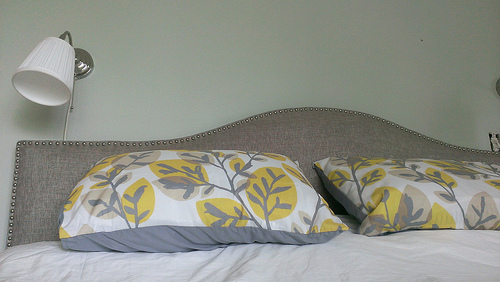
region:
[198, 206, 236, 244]
part of a pillw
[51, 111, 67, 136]
part of a metal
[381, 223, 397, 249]
part of a sheet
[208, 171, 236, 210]
part of a pilloq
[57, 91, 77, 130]
part of a stand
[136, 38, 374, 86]
this is the wall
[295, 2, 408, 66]
the wall is white in color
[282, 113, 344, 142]
this is the bed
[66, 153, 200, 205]
this is a pilow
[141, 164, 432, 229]
the pillows are two in number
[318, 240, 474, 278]
this is a blanket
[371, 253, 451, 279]
the blanket is white in color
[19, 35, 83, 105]
this is a lump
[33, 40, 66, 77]
the lump is white in color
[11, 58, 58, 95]
the lump is off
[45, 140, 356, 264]
pillow on a bed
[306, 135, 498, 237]
pillow on a bed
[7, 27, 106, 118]
light on a wall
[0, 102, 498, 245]
headboard on a bed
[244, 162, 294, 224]
yellow and grey leaf on a pillow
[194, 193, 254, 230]
yellow and grey leaf on a pillow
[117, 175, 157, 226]
yellow and grey leaf on a pillow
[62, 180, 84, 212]
yellow and grey leaf on a pillow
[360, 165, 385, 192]
yellow and grey leaf on a pillow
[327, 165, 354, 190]
yellow and grey leaf on a pillow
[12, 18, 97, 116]
lighting sconce on the wall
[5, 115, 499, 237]
nail detail on headboard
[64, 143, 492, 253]
pillows resting on the bed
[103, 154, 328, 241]
yellow, grey and white pillowcases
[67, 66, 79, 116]
pull cord for lamp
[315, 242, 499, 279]
white comforter on bed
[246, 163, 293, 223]
grey leaf detail printed on fabric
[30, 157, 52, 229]
textured head board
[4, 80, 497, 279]
a queen sized bed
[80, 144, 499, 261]
two pillows in pillowcases on bed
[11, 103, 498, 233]
the headboard for the bed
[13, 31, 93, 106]
a light attached to the wall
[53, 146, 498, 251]
two colorful pillows sitting on the bed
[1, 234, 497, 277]
the white blanket on the bed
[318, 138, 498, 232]
another pillow sitting on the bed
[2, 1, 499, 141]
the wall above the bed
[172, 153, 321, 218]
the branches on the pillow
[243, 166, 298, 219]
a yellow spot on the pillow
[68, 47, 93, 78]
the part of the lamp attached to the wall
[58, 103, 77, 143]
the cord hanging on the wall